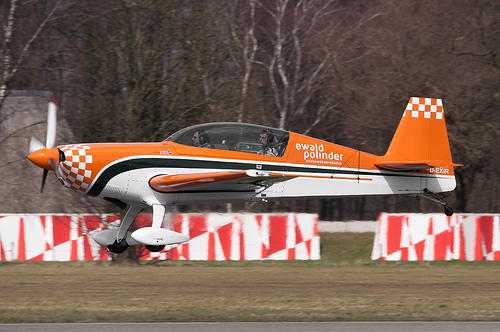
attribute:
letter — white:
[309, 142, 315, 153]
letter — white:
[302, 150, 308, 160]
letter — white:
[308, 149, 316, 163]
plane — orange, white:
[24, 81, 464, 258]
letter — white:
[322, 150, 329, 160]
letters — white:
[290, 140, 351, 165]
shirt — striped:
[262, 148, 275, 158]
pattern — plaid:
[59, 137, 95, 192]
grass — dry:
[13, 261, 464, 312]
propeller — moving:
[25, 99, 66, 208]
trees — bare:
[110, 20, 444, 107]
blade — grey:
[40, 93, 60, 151]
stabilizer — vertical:
[386, 90, 460, 155]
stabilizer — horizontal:
[379, 159, 465, 178]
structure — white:
[130, 203, 187, 255]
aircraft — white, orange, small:
[22, 84, 464, 256]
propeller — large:
[26, 89, 80, 208]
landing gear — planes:
[92, 222, 190, 262]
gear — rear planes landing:
[74, 204, 202, 273]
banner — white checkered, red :
[3, 204, 484, 255]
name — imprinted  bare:
[289, 137, 347, 165]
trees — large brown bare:
[106, 14, 386, 137]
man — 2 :
[191, 123, 214, 149]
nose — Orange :
[29, 128, 95, 190]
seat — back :
[253, 125, 292, 150]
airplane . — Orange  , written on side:
[24, 77, 459, 271]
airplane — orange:
[24, 80, 460, 247]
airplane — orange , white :
[20, 72, 480, 254]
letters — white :
[294, 139, 337, 162]